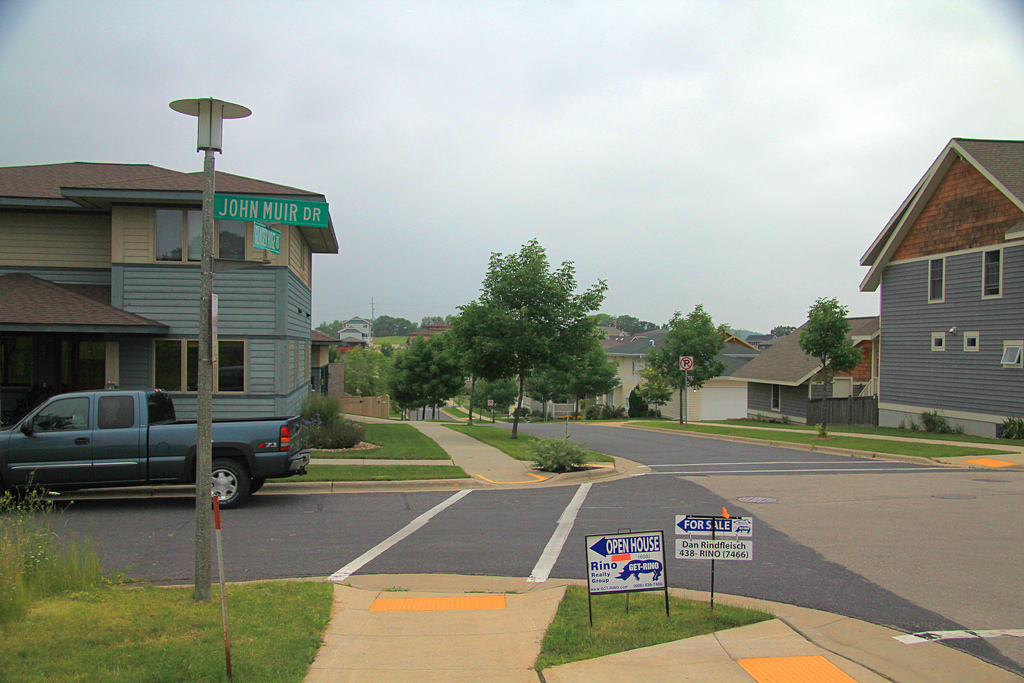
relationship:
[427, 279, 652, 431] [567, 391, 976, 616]
trees by street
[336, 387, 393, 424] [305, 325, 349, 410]
wall attached to building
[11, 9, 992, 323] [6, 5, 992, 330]
clouds in sky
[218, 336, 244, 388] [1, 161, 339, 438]
window on building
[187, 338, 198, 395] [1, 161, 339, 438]
window on building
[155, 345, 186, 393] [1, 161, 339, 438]
window on building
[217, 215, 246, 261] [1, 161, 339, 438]
window on building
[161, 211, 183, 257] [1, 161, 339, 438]
window on building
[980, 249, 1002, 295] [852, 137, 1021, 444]
window on building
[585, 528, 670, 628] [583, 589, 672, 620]
sign with posts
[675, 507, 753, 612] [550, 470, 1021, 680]
sign on corner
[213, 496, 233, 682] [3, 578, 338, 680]
pole on ground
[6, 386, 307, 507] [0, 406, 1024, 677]
truck parked on road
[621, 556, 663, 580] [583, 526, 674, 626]
rhino on sign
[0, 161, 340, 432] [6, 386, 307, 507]
building behind truck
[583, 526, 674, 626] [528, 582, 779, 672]
sign on grass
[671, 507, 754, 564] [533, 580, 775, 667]
sign on grass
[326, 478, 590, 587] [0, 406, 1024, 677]
lines in road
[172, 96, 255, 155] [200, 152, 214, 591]
street light on pole